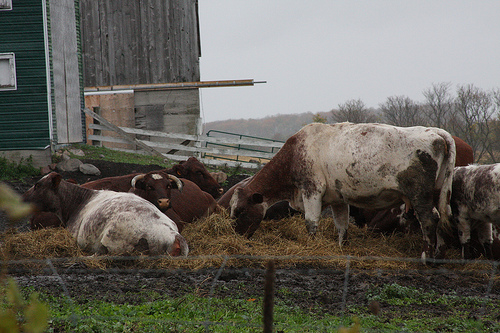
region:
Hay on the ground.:
[182, 202, 345, 263]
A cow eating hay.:
[203, 193, 295, 233]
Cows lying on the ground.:
[38, 162, 203, 262]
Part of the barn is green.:
[4, 3, 59, 150]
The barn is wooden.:
[81, 2, 207, 148]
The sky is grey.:
[229, 15, 401, 57]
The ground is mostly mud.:
[56, 260, 342, 299]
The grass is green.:
[106, 297, 331, 331]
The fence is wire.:
[145, 256, 495, 328]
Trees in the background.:
[401, 92, 499, 157]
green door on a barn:
[7, 9, 94, 141]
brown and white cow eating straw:
[192, 112, 473, 264]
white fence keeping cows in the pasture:
[80, 104, 355, 179]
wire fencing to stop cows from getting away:
[10, 241, 497, 323]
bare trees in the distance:
[285, 77, 496, 153]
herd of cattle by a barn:
[24, 94, 487, 295]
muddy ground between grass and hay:
[31, 241, 478, 330]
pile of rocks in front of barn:
[26, 120, 143, 201]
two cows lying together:
[12, 169, 212, 287]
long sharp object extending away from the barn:
[71, 36, 310, 174]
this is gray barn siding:
[131, 23, 186, 61]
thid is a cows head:
[231, 182, 281, 238]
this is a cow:
[224, 126, 471, 239]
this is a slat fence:
[149, 128, 201, 158]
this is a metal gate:
[204, 129, 271, 163]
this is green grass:
[175, 300, 230, 330]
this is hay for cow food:
[195, 220, 230, 257]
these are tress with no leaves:
[431, 88, 484, 123]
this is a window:
[0, 46, 16, 96]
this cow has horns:
[135, 169, 182, 199]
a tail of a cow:
[436, 133, 459, 250]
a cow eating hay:
[221, 183, 274, 240]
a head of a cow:
[221, 183, 275, 242]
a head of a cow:
[126, 163, 187, 208]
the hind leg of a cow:
[402, 171, 443, 261]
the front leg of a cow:
[295, 188, 326, 250]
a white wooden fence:
[117, 121, 171, 163]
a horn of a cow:
[169, 168, 191, 195]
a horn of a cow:
[127, 167, 147, 195]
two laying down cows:
[20, 166, 194, 268]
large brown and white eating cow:
[218, 106, 465, 281]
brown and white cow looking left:
[20, 159, 191, 281]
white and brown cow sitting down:
[22, 160, 184, 297]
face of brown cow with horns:
[125, 157, 184, 232]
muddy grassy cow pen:
[87, 262, 474, 324]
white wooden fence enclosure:
[85, 103, 292, 172]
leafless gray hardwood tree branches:
[353, 90, 498, 147]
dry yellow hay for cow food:
[182, 206, 405, 266]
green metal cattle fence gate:
[200, 123, 282, 167]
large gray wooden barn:
[87, 5, 211, 125]